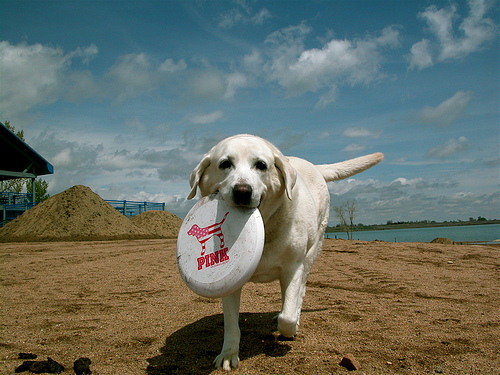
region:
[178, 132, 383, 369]
this is a dog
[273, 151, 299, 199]
this is a dog's ear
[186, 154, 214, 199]
this is a dog's ear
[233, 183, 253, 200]
this is a dog's nose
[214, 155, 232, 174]
this is a dog's eye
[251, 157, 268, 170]
this is a dog's eye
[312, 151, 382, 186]
this is a dog's tail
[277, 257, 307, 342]
this is a dog's leg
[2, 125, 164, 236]
this is a building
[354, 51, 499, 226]
this is the sky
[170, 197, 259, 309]
A white frisbee disk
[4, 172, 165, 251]
A pile of brown sand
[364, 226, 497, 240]
A blue water on the background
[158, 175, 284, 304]
A disk in the dogs' mouth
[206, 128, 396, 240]
A big white dog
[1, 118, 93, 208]
Cottage at the back of sand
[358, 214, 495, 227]
Trees on the baclground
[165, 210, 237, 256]
A dog printed on white disk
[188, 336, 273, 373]
Feet on the brown sand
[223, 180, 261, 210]
The white dogs' nose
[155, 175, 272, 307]
flying disk in dog mouth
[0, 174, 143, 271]
mound of sand in back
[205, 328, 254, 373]
dog white paw on ground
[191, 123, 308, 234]
white lab with black eyes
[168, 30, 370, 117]
blue skyes with white clouds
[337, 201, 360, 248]
dead tree in background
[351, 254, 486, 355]
sandy beach messed up sand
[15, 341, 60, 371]
rocks on sandy beach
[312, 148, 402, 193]
dog tail sky background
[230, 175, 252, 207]
black dog nose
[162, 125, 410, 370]
dog holding a frisbee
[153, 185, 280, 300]
red and white frisbee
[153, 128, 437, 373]
dog on the sand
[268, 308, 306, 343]
front paw is in the air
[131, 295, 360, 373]
shadow on the ground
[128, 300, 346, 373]
shadow from the dog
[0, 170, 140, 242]
a mound of sand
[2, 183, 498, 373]
sand on the ground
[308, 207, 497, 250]
small body of water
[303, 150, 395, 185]
tail swishing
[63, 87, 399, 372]
a dog walking across the sand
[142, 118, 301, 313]
a dog holding a frisbee in its mouth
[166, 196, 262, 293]
a frisbee with the word Pink on it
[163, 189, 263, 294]
a frisbee with a picture of a dog on it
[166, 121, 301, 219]
the head of a dog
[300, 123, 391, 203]
the tail of a dog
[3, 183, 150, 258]
a big pile of dirt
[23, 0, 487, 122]
clouds in a blue sky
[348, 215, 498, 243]
a body of water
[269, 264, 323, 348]
the legs of a dog